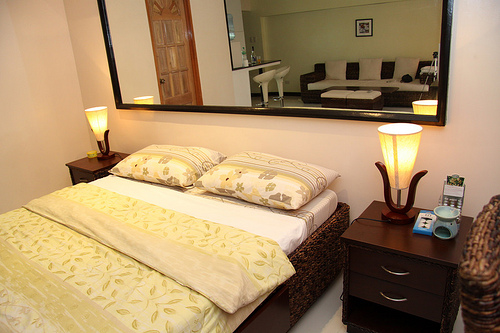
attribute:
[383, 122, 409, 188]
lamp — glowing, illuminated, wooden, conical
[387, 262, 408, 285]
handles — silver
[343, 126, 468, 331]
drawers — wooden, brown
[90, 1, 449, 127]
frame — wooden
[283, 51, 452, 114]
couch — reflected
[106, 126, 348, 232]
pillows — fluffy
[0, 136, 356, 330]
bed — queen-size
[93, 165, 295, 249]
sheet — white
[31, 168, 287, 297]
bedspread — turned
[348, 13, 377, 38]
picture — square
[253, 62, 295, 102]
chairs — white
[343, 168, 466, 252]
table — wooden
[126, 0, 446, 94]
mirror — wide, large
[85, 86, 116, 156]
lamp — illuminated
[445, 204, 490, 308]
basket — brown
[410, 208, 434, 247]
remote — blue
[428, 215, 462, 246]
candle holder — blue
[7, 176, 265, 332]
comforter — lavish